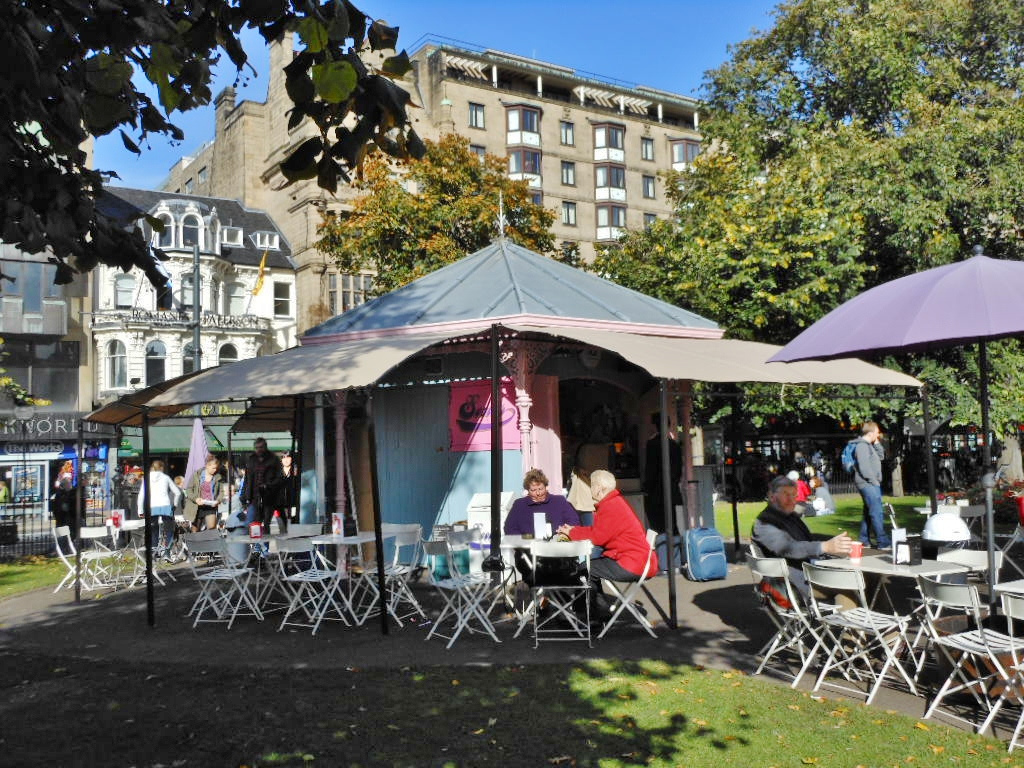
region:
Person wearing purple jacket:
[505, 468, 594, 624]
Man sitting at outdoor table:
[749, 476, 854, 620]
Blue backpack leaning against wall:
[680, 521, 731, 583]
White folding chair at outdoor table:
[522, 535, 600, 650]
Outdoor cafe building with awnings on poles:
[81, 189, 930, 632]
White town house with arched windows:
[87, 183, 303, 409]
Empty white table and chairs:
[183, 522, 430, 630]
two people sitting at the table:
[497, 454, 668, 626]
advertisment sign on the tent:
[449, 377, 510, 454]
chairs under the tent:
[174, 524, 380, 632]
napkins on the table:
[895, 536, 916, 560]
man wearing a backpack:
[830, 413, 900, 547]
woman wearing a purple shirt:
[501, 464, 582, 537]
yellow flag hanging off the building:
[248, 244, 269, 314]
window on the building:
[583, 114, 631, 171]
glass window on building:
[266, 273, 287, 311]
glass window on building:
[507, 144, 518, 171]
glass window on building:
[507, 103, 518, 129]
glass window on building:
[517, 100, 530, 127]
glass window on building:
[522, 147, 535, 174]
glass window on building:
[564, 198, 574, 221]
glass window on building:
[608, 120, 619, 150]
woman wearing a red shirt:
[569, 487, 656, 563]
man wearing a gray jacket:
[850, 433, 885, 485]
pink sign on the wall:
[443, 369, 560, 453]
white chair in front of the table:
[284, 521, 362, 613]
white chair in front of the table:
[916, 569, 1019, 724]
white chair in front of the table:
[524, 527, 598, 652]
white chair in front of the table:
[370, 527, 446, 629]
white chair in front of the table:
[173, 525, 266, 627]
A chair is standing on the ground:
[744, 556, 837, 689]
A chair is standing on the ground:
[803, 562, 918, 705]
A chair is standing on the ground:
[51, 527, 103, 589]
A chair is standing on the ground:
[179, 528, 265, 626]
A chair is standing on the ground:
[283, 535, 356, 630]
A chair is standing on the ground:
[367, 524, 426, 624]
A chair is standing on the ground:
[422, 540, 503, 640]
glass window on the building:
[460, 96, 480, 122]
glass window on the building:
[558, 115, 571, 147]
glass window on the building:
[555, 160, 578, 180]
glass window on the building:
[557, 201, 573, 224]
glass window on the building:
[637, 134, 651, 155]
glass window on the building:
[267, 277, 291, 315]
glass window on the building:
[143, 349, 164, 384]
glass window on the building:
[175, 222, 205, 248]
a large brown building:
[218, 54, 727, 299]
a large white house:
[106, 199, 304, 416]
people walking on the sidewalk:
[41, 446, 269, 538]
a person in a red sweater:
[572, 474, 656, 618]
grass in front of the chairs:
[449, 650, 924, 762]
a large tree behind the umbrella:
[629, 104, 1000, 422]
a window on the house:
[144, 348, 171, 388]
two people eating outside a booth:
[500, 467, 655, 648]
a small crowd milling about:
[115, 443, 287, 555]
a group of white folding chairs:
[178, 512, 384, 633]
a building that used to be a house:
[86, 186, 292, 545]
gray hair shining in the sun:
[585, 465, 620, 508]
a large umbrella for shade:
[772, 246, 1022, 360]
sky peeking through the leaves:
[78, 21, 263, 190]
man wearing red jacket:
[554, 459, 647, 616]